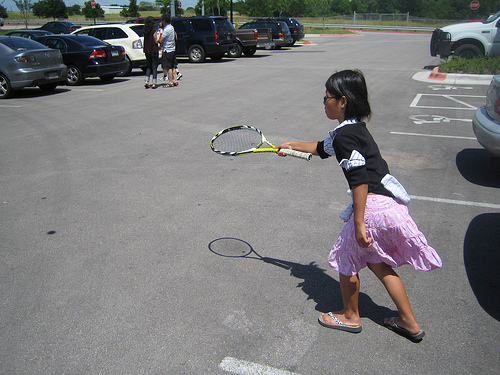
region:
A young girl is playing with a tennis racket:
[201, 56, 449, 351]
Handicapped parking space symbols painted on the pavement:
[401, 79, 477, 141]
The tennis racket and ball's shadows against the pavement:
[31, 198, 298, 282]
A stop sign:
[464, 0, 485, 20]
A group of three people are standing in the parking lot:
[139, 12, 184, 96]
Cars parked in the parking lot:
[3, 16, 306, 88]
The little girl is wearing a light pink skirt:
[299, 67, 443, 350]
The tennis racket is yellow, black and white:
[202, 112, 315, 162]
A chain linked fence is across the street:
[313, 4, 444, 25]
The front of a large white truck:
[429, 4, 498, 64]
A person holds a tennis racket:
[213, 121, 319, 172]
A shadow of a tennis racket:
[207, 228, 284, 277]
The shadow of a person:
[205, 230, 397, 332]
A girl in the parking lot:
[322, 70, 427, 349]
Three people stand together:
[142, 14, 184, 91]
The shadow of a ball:
[40, 224, 60, 242]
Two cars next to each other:
[6, 35, 124, 87]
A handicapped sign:
[408, 109, 476, 129]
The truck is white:
[441, 13, 499, 53]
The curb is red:
[431, 63, 448, 80]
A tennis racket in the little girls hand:
[203, 117, 313, 182]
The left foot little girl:
[309, 298, 371, 337]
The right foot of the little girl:
[378, 300, 429, 344]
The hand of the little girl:
[343, 219, 380, 249]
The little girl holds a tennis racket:
[205, 60, 446, 350]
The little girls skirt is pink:
[330, 188, 445, 278]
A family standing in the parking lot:
[133, 11, 190, 91]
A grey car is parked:
[1, 25, 66, 100]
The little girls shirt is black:
[306, 113, 427, 221]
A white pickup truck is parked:
[428, 3, 497, 68]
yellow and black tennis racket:
[156, 114, 287, 213]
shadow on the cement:
[147, 204, 314, 330]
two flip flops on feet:
[296, 305, 441, 357]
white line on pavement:
[162, 345, 334, 371]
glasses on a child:
[309, 83, 341, 104]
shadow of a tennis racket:
[192, 223, 277, 277]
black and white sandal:
[277, 303, 364, 343]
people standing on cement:
[113, 13, 207, 98]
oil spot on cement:
[28, 194, 85, 273]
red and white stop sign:
[75, 0, 106, 22]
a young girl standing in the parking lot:
[272, 70, 442, 342]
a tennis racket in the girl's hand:
[207, 123, 311, 159]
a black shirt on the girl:
[316, 118, 411, 202]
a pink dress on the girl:
[326, 188, 441, 275]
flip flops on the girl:
[318, 310, 425, 337]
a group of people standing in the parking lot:
[142, 15, 182, 88]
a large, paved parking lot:
[0, 28, 498, 374]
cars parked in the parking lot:
[0, 15, 499, 190]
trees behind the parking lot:
[1, 0, 499, 26]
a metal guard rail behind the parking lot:
[0, 18, 440, 34]